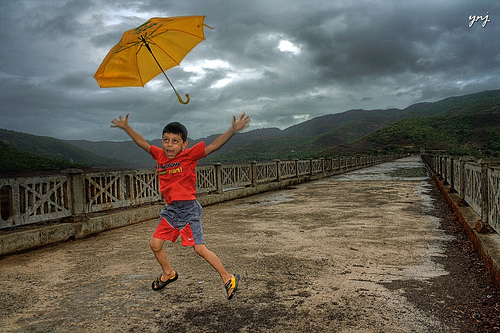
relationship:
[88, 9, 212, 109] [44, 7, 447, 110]
umbrealla in sky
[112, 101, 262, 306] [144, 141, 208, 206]
boy wearing red shirt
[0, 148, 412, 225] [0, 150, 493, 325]
fence near ground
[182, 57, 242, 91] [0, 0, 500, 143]
sunlight peeping through clouds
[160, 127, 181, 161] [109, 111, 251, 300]
face of boy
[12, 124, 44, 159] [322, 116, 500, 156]
grass on hill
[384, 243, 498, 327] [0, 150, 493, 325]
dirt on ground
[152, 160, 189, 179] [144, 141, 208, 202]
logo on red shirt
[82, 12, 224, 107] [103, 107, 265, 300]
umbrella over boy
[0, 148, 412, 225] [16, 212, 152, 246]
fence on side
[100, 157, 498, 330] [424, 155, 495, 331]
gravel on side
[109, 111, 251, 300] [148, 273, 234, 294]
boy wearing sandals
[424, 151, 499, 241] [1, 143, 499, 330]
fence on right side of bridge